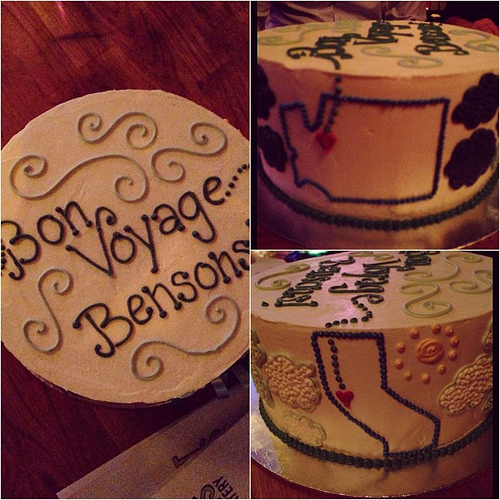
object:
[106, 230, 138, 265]
letter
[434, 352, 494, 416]
design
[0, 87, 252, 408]
white frosting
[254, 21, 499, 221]
white frosting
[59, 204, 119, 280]
letter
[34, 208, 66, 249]
letter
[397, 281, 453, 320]
design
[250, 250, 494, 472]
decorated cake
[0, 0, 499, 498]
three photos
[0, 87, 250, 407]
cake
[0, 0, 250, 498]
table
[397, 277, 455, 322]
design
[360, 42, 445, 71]
design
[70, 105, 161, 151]
design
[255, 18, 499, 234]
party cake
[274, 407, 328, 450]
decor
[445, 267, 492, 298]
design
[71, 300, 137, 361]
letter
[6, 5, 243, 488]
table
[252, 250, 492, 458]
frosting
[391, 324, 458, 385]
design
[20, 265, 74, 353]
design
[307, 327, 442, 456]
california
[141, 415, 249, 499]
menus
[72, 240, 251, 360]
bensons